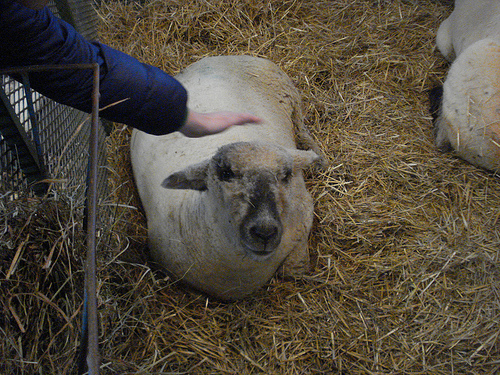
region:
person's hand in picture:
[185, 103, 256, 143]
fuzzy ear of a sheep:
[164, 158, 209, 199]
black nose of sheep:
[242, 183, 284, 252]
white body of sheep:
[139, 39, 320, 316]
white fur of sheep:
[137, 156, 170, 184]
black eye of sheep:
[215, 160, 245, 184]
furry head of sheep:
[160, 139, 327, 256]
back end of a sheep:
[408, 54, 494, 176]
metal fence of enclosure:
[64, 75, 117, 370]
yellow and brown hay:
[320, 201, 450, 343]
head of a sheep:
[208, 130, 308, 244]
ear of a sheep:
[286, 128, 337, 173]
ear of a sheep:
[160, 147, 227, 204]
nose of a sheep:
[246, 216, 291, 249]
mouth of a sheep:
[245, 239, 276, 253]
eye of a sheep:
[208, 162, 231, 192]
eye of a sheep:
[280, 165, 297, 190]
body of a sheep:
[128, 55, 288, 217]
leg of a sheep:
[285, 232, 309, 287]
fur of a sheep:
[266, 99, 285, 147]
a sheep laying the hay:
[130, 48, 320, 299]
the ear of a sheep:
[282, 140, 319, 176]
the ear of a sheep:
[160, 155, 210, 193]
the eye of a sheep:
[214, 163, 241, 188]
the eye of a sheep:
[277, 163, 297, 188]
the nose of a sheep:
[245, 217, 282, 242]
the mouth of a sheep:
[242, 244, 278, 258]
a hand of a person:
[179, 96, 266, 142]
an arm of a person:
[5, 3, 191, 135]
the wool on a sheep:
[222, 65, 272, 102]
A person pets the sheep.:
[2, 0, 323, 301]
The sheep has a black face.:
[161, 140, 321, 260]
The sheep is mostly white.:
[126, 54, 325, 305]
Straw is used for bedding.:
[99, 2, 499, 374]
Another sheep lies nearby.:
[427, 0, 499, 173]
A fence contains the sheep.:
[1, 0, 109, 373]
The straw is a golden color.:
[97, 0, 499, 374]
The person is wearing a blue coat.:
[3, 1, 185, 139]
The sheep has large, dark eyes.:
[160, 140, 327, 260]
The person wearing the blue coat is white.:
[182, 100, 264, 137]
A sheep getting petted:
[123, 50, 338, 309]